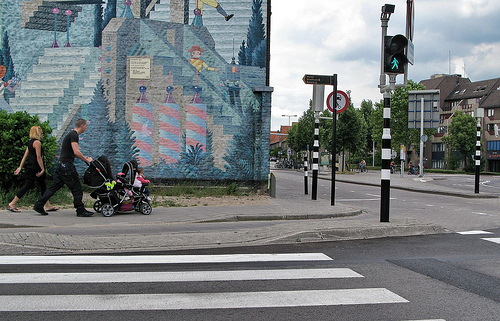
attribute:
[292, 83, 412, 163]
sign — one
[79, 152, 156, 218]
baby stroller — black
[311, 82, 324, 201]
pole — one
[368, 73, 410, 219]
pole — one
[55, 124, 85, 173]
shirt — black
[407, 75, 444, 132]
building — Gray and Tan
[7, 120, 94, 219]
couple — walking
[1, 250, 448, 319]
stripes — white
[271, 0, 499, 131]
sky — overcast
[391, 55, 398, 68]
person — green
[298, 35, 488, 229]
poles — white, black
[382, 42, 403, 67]
sign — green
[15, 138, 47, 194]
clothes — black